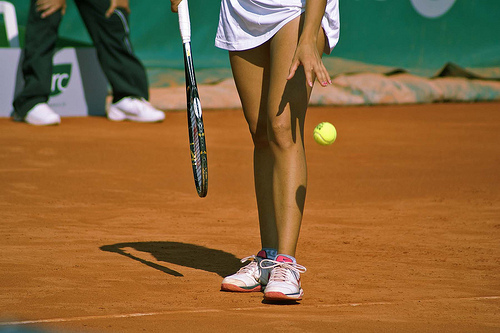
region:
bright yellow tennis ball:
[313, 120, 337, 144]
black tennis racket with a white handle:
[169, 0, 211, 196]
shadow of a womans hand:
[281, 65, 313, 147]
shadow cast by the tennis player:
[96, 231, 244, 283]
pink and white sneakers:
[220, 245, 305, 299]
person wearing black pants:
[10, 2, 165, 122]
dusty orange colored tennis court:
[19, 104, 486, 324]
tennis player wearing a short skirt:
[211, 0, 346, 310]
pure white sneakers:
[14, 94, 165, 126]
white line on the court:
[13, 284, 485, 329]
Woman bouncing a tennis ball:
[167, 0, 344, 306]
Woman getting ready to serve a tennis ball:
[166, 0, 341, 303]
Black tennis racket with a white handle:
[172, 0, 209, 202]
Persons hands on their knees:
[23, 0, 136, 22]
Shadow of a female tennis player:
[98, 238, 250, 285]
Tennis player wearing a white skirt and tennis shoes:
[167, 0, 342, 305]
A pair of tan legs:
[223, 8, 325, 255]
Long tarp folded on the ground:
[117, 59, 499, 111]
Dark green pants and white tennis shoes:
[10, 0, 161, 125]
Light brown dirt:
[0, 102, 499, 331]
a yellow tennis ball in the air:
[311, 119, 337, 145]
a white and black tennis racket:
[178, 4, 208, 197]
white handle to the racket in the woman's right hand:
[169, 0, 191, 45]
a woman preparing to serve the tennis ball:
[168, 0, 340, 303]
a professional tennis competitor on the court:
[168, 0, 494, 332]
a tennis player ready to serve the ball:
[167, 0, 498, 330]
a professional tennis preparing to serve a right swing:
[169, 0, 341, 302]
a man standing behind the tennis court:
[8, 0, 167, 124]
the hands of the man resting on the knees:
[32, 1, 131, 19]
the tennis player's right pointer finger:
[170, 0, 182, 14]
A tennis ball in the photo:
[310, 116, 340, 152]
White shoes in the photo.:
[222, 251, 307, 302]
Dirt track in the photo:
[384, 208, 465, 295]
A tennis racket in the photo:
[170, 7, 220, 199]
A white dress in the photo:
[201, 0, 349, 50]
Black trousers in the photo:
[0, 4, 153, 110]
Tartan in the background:
[335, 44, 477, 101]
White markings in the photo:
[326, 282, 473, 313]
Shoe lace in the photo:
[262, 254, 310, 273]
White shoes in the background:
[22, 96, 180, 136]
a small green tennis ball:
[313, 121, 341, 146]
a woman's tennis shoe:
[263, 252, 305, 305]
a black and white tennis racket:
[170, 3, 219, 200]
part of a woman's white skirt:
[213, 3, 347, 53]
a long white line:
[7, 300, 267, 331]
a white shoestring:
[260, 254, 307, 281]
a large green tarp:
[3, 0, 498, 86]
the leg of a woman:
[256, 2, 333, 257]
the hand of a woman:
[281, 35, 331, 90]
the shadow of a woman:
[94, 222, 240, 293]